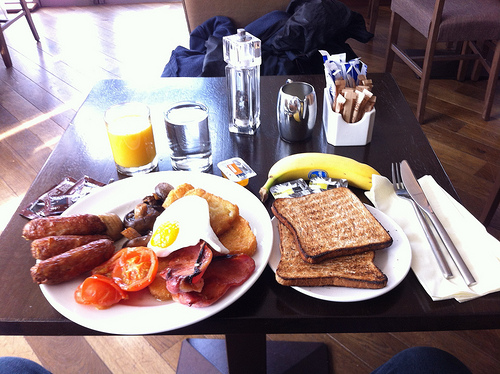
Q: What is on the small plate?
A: Two pieces of toast.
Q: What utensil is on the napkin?
A: A knife.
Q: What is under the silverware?
A: Two napkins.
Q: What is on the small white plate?
A: Brown toast.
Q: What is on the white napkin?
A: Knife and fork.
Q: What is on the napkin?
A: Silver utensils.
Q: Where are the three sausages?
A: On the large white plates.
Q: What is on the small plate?
A: Two slices of toast.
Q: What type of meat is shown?
A: Sausage links.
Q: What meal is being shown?
A: Breakfast.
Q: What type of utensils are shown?
A: Fork and knife.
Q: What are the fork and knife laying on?
A: Napkin.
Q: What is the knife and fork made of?
A: Metal.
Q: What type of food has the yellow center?
A: Egg.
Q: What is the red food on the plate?
A: Tomatoes.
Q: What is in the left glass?
A: Orange juice.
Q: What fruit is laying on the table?
A: Banana.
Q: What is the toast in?
A: Saucer.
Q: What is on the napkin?
A: Knife and fork.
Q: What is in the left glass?
A: Orange juice.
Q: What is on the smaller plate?
A: Toast.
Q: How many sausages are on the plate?
A: 3.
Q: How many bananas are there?
A: 1.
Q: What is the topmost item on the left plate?
A: A fried egg.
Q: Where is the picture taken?
A: Dining room.